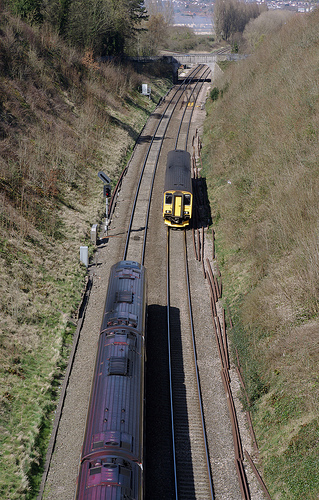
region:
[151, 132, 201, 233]
A train on the tracks.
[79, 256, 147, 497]
Long train on the tracks.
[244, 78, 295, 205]
The grass is turning brown.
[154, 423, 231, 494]
Gravel around the tracks.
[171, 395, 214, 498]
The tracks are metal.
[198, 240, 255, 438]
Boards next to the tracks.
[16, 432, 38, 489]
White in the grass.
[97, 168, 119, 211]
Stop sign on the tracks.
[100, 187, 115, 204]
The red light is shining.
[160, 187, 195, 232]
The front of the train is yellow.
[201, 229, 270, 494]
logs strewn along railroad tracks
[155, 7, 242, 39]
body of water at base of hill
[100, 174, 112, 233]
traffic light for trains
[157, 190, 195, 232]
rear on yellow train car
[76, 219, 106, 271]
boxes house track electronics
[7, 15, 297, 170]
the hollowed out area of land made for tracks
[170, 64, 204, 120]
area made to switch tracks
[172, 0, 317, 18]
many buildings across the water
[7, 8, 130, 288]
long dry vegetation on hill side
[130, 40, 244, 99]
a bridge crosses the tracks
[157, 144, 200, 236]
small train on the tracks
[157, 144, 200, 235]
black and yellow train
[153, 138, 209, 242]
train with two cars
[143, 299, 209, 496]
shadow from the train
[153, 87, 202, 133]
two parallel train tracks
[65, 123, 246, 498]
two trains on the trakcs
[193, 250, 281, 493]
small rods laying along the tracks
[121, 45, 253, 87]
bridge over the tracks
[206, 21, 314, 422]
dead grass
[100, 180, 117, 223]
light flashing red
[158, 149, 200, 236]
a single yellow train car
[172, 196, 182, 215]
the door is yellow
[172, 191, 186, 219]
the door to the trsain car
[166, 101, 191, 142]
the train tracks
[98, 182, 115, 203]
the red stop light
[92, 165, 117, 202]
the light signal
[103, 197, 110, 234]
the pole for the signal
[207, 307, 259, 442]
rails on the ground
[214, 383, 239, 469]
pebbles by the train tracks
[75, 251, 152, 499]
A train stooped at a light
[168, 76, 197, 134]
Train tracks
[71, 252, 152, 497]
red train moving on tracks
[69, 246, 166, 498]
train moving on tracks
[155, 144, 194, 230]
yellow train moving on tracks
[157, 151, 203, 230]
train moving on tracks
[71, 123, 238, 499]
two trains moving on tracks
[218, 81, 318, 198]
grass covered hill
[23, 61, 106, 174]
grass covered hill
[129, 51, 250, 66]
bridge over tracks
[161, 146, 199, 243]
yellow train on train tracks